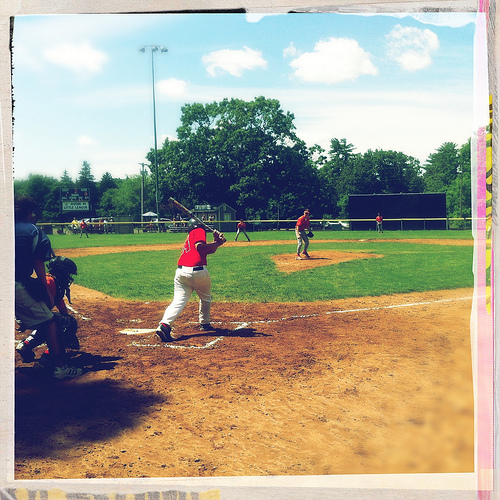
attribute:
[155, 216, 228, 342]
man — playing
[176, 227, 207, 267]
shirt — red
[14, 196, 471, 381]
game — baseball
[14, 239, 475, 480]
dirt — brown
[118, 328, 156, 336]
plate — white, home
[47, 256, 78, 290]
mask — black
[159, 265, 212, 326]
pants — white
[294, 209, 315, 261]
pitcher — here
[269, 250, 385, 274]
mound — pitcher's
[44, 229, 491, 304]
grass — cut, green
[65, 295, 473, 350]
path — white, paint, first base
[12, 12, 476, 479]
outside — sunny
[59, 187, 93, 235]
sign — black, white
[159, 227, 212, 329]
uniform — white, red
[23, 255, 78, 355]
uniform — white, red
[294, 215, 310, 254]
uniform — white, red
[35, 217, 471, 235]
fence — yellow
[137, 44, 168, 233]
pole — metal